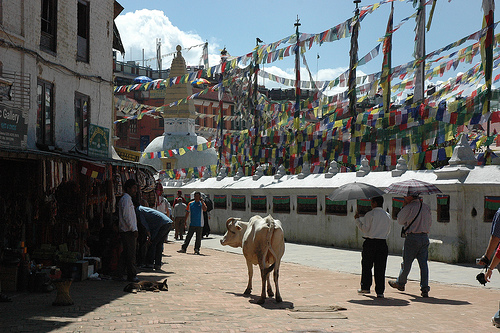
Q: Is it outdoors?
A: Yes, it is outdoors.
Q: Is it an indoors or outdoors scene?
A: It is outdoors.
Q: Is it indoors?
A: No, it is outdoors.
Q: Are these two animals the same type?
A: No, they are dogs and cows.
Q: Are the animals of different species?
A: Yes, they are dogs and cows.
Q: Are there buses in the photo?
A: No, there are no buses.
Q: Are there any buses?
A: No, there are no buses.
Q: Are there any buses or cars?
A: No, there are no buses or cars.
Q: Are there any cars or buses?
A: No, there are no buses or cars.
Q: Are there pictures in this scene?
A: No, there are no pictures.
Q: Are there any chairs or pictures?
A: No, there are no pictures or chairs.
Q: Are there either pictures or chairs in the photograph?
A: No, there are no pictures or chairs.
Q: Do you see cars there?
A: No, there are no cars.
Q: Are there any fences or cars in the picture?
A: No, there are no cars or fences.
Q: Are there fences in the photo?
A: No, there are no fences.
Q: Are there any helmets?
A: No, there are no helmets.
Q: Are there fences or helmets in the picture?
A: No, there are no helmets or fences.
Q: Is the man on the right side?
A: Yes, the man is on the right of the image.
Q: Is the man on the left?
A: No, the man is on the right of the image.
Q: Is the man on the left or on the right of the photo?
A: The man is on the right of the image.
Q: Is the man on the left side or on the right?
A: The man is on the right of the image.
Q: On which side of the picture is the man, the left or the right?
A: The man is on the right of the image.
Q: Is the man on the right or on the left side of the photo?
A: The man is on the right of the image.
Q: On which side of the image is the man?
A: The man is on the right of the image.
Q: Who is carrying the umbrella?
A: The man is carrying the umbrella.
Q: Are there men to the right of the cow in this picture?
A: Yes, there is a man to the right of the cow.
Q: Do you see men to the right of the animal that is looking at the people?
A: Yes, there is a man to the right of the cow.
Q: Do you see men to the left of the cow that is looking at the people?
A: No, the man is to the right of the cow.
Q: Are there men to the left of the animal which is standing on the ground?
A: No, the man is to the right of the cow.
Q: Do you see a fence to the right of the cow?
A: No, there is a man to the right of the cow.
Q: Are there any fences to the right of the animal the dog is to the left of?
A: No, there is a man to the right of the cow.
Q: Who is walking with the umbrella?
A: The man is walking with the umbrella.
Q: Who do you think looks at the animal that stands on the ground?
A: The man looks at the cow.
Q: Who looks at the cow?
A: The man looks at the cow.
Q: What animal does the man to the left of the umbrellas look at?
A: The man looks at the cow.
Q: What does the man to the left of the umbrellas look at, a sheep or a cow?
A: The man looks at a cow.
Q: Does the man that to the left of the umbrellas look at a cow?
A: Yes, the man looks at a cow.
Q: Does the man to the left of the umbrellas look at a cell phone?
A: No, the man looks at a cow.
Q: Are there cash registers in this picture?
A: No, there are no cash registers.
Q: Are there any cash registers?
A: No, there are no cash registers.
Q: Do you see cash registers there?
A: No, there are no cash registers.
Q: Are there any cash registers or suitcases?
A: No, there are no cash registers or suitcases.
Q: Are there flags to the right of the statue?
A: Yes, there are flags to the right of the statue.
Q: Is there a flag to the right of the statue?
A: Yes, there are flags to the right of the statue.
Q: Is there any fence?
A: No, there are no fences.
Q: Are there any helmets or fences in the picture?
A: No, there are no fences or helmets.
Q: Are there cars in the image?
A: No, there are no cars.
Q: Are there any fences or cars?
A: No, there are no cars or fences.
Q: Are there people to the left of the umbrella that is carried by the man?
A: Yes, there are people to the left of the umbrella.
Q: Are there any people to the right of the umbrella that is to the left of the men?
A: No, the people are to the left of the umbrella.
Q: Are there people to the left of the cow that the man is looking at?
A: Yes, there are people to the left of the cow.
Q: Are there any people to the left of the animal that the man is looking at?
A: Yes, there are people to the left of the cow.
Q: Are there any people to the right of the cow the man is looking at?
A: No, the people are to the left of the cow.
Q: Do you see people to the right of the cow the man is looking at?
A: No, the people are to the left of the cow.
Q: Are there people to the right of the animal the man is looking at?
A: No, the people are to the left of the cow.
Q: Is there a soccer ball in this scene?
A: No, there are no soccer balls.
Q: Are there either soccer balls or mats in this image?
A: No, there are no soccer balls or mats.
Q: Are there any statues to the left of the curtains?
A: Yes, there is a statue to the left of the curtains.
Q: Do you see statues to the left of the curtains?
A: Yes, there is a statue to the left of the curtains.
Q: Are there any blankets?
A: No, there are no blankets.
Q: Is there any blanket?
A: No, there are no blankets.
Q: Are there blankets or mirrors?
A: No, there are no blankets or mirrors.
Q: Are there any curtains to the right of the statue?
A: Yes, there are curtains to the right of the statue.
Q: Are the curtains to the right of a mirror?
A: No, the curtains are to the right of the statue.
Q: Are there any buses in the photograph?
A: No, there are no buses.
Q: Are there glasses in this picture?
A: No, there are no glasses.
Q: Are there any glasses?
A: No, there are no glasses.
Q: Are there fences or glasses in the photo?
A: No, there are no glasses or fences.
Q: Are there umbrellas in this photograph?
A: Yes, there is an umbrella.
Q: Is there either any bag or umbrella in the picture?
A: Yes, there is an umbrella.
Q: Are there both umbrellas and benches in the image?
A: No, there is an umbrella but no benches.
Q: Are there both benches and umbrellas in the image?
A: No, there is an umbrella but no benches.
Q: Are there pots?
A: No, there are no pots.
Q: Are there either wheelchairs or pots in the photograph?
A: No, there are no pots or wheelchairs.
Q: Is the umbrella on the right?
A: Yes, the umbrella is on the right of the image.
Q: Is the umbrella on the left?
A: No, the umbrella is on the right of the image.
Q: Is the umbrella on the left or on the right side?
A: The umbrella is on the right of the image.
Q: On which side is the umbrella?
A: The umbrella is on the right of the image.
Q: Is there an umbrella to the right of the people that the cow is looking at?
A: Yes, there is an umbrella to the right of the people.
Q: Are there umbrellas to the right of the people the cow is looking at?
A: Yes, there is an umbrella to the right of the people.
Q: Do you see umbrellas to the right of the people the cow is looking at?
A: Yes, there is an umbrella to the right of the people.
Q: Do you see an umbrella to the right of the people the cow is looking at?
A: Yes, there is an umbrella to the right of the people.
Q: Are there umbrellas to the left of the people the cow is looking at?
A: No, the umbrella is to the right of the people.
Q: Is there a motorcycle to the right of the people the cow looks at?
A: No, there is an umbrella to the right of the people.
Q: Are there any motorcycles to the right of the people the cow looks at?
A: No, there is an umbrella to the right of the people.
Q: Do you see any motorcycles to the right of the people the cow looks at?
A: No, there is an umbrella to the right of the people.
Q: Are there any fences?
A: No, there are no fences.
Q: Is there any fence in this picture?
A: No, there are no fences.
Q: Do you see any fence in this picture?
A: No, there are no fences.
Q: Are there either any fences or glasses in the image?
A: No, there are no fences or glasses.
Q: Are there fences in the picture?
A: No, there are no fences.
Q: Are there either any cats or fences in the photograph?
A: No, there are no fences or cats.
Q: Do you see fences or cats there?
A: No, there are no fences or cats.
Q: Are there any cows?
A: Yes, there is a cow.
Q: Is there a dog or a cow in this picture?
A: Yes, there is a cow.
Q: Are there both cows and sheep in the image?
A: No, there is a cow but no sheep.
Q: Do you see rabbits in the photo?
A: No, there are no rabbits.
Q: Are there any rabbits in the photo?
A: No, there are no rabbits.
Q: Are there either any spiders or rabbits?
A: No, there are no rabbits or spiders.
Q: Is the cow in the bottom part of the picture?
A: Yes, the cow is in the bottom of the image.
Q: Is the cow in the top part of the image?
A: No, the cow is in the bottom of the image.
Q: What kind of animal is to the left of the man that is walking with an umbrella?
A: The animal is a cow.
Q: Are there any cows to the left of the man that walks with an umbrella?
A: Yes, there is a cow to the left of the man.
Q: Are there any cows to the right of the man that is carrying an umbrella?
A: No, the cow is to the left of the man.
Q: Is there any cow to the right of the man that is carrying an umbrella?
A: No, the cow is to the left of the man.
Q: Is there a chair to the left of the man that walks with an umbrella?
A: No, there is a cow to the left of the man.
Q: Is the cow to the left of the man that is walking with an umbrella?
A: Yes, the cow is to the left of the man.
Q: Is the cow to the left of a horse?
A: No, the cow is to the left of the man.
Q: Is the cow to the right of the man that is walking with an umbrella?
A: No, the cow is to the left of the man.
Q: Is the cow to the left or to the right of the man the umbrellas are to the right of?
A: The cow is to the left of the man.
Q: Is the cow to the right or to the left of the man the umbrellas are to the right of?
A: The cow is to the left of the man.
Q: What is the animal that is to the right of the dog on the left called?
A: The animal is a cow.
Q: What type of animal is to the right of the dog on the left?
A: The animal is a cow.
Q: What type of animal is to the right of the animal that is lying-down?
A: The animal is a cow.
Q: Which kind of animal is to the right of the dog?
A: The animal is a cow.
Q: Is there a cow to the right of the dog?
A: Yes, there is a cow to the right of the dog.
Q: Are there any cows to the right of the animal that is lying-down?
A: Yes, there is a cow to the right of the dog.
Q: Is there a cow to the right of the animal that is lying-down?
A: Yes, there is a cow to the right of the dog.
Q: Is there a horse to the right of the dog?
A: No, there is a cow to the right of the dog.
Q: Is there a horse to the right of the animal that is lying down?
A: No, there is a cow to the right of the dog.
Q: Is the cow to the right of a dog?
A: Yes, the cow is to the right of a dog.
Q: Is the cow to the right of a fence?
A: No, the cow is to the right of a dog.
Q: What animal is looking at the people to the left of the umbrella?
A: The cow is looking at the people.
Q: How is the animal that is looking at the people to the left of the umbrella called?
A: The animal is a cow.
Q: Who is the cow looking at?
A: The cow is looking at the people.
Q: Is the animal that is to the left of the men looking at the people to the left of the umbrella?
A: Yes, the cow is looking at the people.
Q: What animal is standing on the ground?
A: The cow is standing on the ground.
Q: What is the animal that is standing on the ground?
A: The animal is a cow.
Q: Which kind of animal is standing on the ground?
A: The animal is a cow.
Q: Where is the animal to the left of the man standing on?
A: The cow is standing on the ground.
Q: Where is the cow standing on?
A: The cow is standing on the ground.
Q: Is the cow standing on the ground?
A: Yes, the cow is standing on the ground.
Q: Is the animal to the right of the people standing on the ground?
A: Yes, the cow is standing on the ground.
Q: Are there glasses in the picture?
A: No, there are no glasses.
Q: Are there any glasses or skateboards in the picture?
A: No, there are no glasses or skateboards.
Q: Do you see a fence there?
A: No, there are no fences.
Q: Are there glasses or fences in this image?
A: No, there are no fences or glasses.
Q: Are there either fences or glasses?
A: No, there are no fences or glasses.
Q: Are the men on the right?
A: Yes, the men are on the right of the image.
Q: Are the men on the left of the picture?
A: No, the men are on the right of the image.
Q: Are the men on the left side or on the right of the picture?
A: The men are on the right of the image.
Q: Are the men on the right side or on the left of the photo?
A: The men are on the right of the image.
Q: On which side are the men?
A: The men are on the right of the image.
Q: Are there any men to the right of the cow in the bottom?
A: Yes, there are men to the right of the cow.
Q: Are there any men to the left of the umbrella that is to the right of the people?
A: No, the men are to the right of the umbrella.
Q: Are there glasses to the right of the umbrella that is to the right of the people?
A: No, there are men to the right of the umbrella.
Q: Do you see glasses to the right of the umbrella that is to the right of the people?
A: No, there are men to the right of the umbrella.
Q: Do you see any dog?
A: Yes, there is a dog.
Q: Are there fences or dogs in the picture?
A: Yes, there is a dog.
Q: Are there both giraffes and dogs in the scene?
A: No, there is a dog but no giraffes.